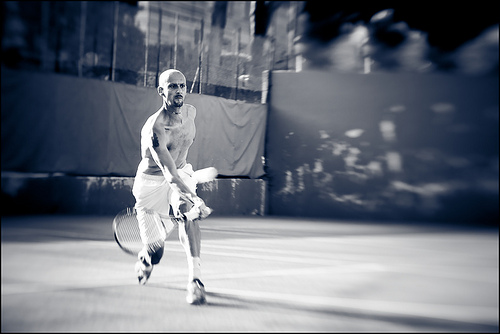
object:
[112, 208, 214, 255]
tennis racket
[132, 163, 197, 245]
shorts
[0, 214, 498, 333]
tennis court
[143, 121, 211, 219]
arm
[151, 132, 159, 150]
tattoo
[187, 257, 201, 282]
socks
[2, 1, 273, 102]
fence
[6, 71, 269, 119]
background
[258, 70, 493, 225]
wall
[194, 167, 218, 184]
tennis ball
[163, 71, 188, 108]
face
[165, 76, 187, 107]
expression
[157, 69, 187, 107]
head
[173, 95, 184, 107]
goatee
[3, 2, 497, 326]
image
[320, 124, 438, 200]
markings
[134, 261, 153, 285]
sneakers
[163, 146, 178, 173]
bicep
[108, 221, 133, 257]
edge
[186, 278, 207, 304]
shoe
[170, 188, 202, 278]
leg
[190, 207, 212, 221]
handle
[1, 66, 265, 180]
wind screen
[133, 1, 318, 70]
buildings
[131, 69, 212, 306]
man